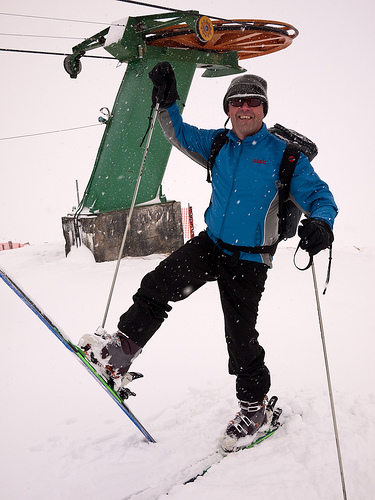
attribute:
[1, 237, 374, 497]
snow — white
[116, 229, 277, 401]
pants — black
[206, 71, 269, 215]
man — tall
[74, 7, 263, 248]
metal — green